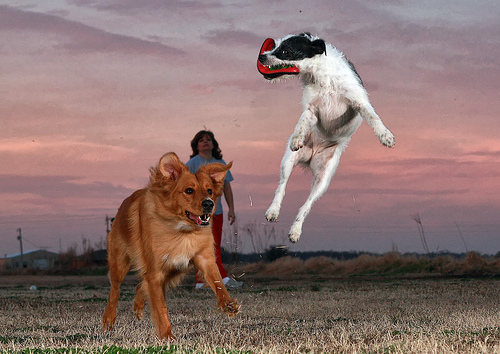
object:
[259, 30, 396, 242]
dog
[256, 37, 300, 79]
frisbee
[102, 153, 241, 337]
dog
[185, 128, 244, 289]
woman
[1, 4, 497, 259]
sky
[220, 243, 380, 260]
bushes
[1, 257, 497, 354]
grass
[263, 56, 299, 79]
mouth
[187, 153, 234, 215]
shirt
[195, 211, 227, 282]
pants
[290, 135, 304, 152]
paw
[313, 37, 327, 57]
ear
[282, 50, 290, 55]
eye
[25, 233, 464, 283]
distance